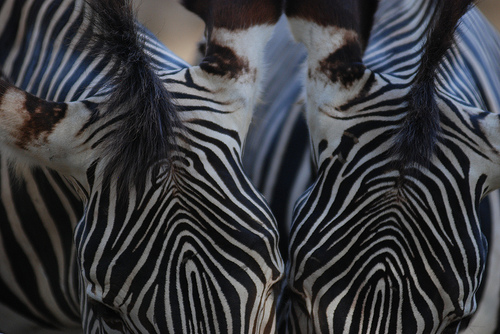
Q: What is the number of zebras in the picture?
A: Two.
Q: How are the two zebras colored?
A: Black and white.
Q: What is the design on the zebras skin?
A: Stripes.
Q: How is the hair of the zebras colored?
A: Black.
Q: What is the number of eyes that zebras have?
A: Two.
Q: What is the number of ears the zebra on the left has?
A: Two.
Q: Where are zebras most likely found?
A: Africa.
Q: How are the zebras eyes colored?
A: Black.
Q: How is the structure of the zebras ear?
A: Pointy.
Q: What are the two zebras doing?
A: Touching faces.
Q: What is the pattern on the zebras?
A: Stripes.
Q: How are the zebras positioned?
A: Cheek to cheek.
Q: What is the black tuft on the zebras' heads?
A: Mane.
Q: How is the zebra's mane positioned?
A: Straight up.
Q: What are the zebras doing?
A: Standing close together.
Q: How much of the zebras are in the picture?
A: Their heads and part of their necks.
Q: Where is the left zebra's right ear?
A: On the side away from the other zebra.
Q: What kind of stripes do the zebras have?
A: Black and white.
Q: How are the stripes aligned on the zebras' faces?
A: Blending into each other in the middle.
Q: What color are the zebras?
A: Black and white.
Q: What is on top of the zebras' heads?
A: Hair.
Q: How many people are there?
A: 0.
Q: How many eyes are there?
A: 4.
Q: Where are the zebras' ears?
A: On top of head.